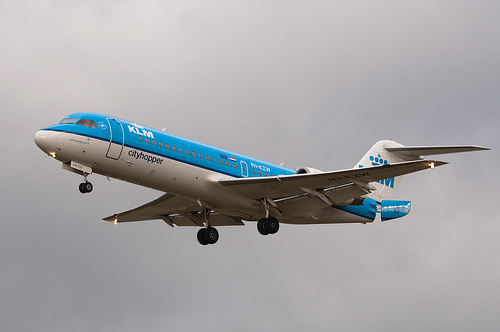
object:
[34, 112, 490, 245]
airplane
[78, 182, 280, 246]
wheels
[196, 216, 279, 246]
wheels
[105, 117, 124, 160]
door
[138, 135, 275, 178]
windows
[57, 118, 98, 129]
windows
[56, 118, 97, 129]
cockpit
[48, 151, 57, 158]
light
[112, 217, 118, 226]
light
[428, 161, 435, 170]
light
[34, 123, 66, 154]
nose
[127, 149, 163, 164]
cityhopper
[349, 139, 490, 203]
tail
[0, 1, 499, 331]
clouds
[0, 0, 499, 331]
sky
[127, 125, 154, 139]
klm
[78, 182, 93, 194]
front wheels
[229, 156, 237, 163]
flag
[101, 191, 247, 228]
wing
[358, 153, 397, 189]
logo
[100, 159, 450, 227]
wings